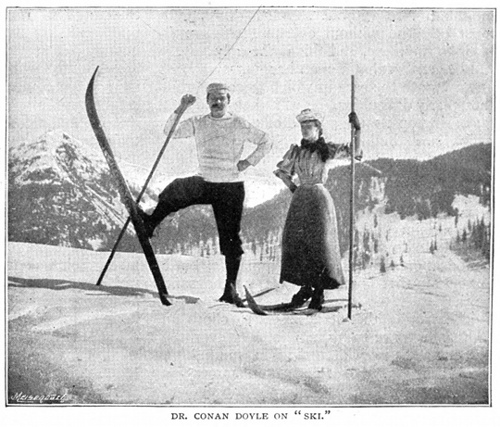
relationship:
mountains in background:
[13, 130, 482, 244] [15, 96, 457, 247]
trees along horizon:
[130, 138, 477, 262] [12, 125, 466, 254]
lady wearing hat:
[275, 110, 363, 313] [297, 108, 321, 120]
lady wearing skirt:
[275, 110, 363, 313] [279, 182, 344, 286]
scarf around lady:
[296, 136, 329, 161] [281, 108, 352, 291]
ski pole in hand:
[344, 76, 363, 324] [348, 110, 363, 128]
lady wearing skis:
[275, 110, 363, 313] [241, 287, 361, 312]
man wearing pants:
[137, 83, 272, 305] [130, 174, 253, 304]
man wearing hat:
[137, 83, 272, 305] [206, 83, 228, 95]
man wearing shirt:
[137, 83, 272, 305] [161, 112, 271, 186]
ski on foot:
[83, 66, 171, 309] [135, 204, 155, 242]